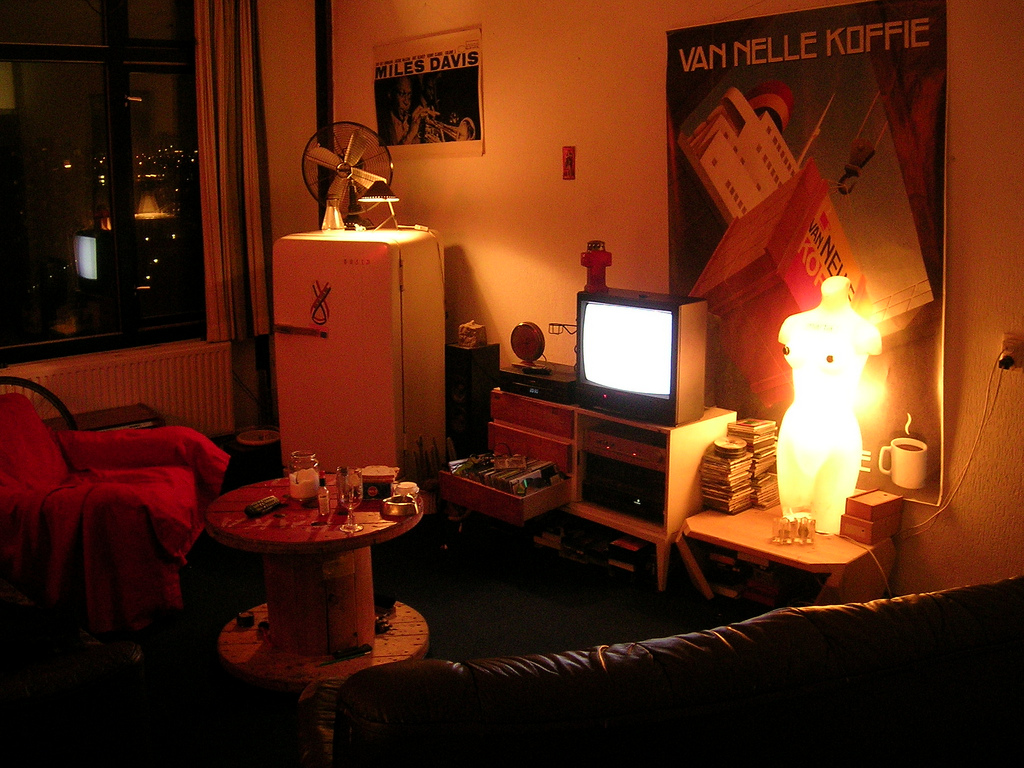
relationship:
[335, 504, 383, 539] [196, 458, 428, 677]
case on table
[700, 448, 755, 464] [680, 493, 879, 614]
case on table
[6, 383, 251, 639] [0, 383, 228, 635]
chair covered with chair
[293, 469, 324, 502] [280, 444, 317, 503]
candle in jar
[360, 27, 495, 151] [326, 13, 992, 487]
poster hanging on wall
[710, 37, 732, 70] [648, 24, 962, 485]
letter on sign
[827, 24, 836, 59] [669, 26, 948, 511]
letter on sign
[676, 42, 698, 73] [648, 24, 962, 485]
letter on sign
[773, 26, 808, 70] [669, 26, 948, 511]
letter on sign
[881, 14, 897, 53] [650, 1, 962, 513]
letter on sign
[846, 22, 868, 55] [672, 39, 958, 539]
letter on sign